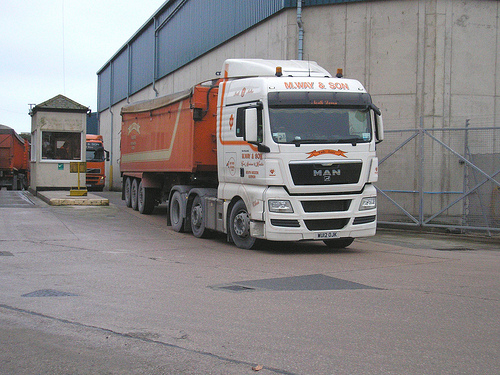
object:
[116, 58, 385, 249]
truck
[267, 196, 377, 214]
headlights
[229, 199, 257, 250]
front tire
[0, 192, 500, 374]
pavement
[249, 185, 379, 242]
grill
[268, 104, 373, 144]
windshield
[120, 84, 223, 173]
container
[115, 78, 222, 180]
truckload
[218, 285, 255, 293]
vent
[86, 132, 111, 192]
orange truck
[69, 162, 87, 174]
sign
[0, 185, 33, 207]
ramp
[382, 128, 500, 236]
gate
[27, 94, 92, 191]
shelter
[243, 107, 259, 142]
side mirror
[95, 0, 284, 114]
blue siding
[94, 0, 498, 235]
building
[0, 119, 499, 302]
lot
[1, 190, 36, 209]
track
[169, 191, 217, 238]
center wheels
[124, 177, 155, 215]
back wheels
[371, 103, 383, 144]
right mirror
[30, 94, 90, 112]
black roof